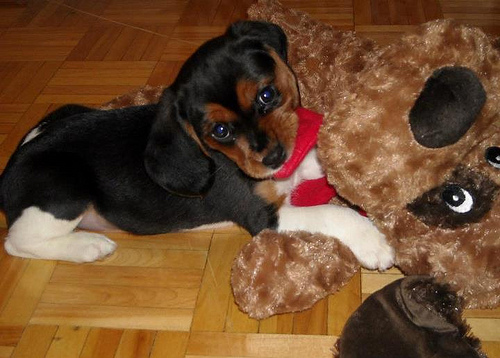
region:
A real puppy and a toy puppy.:
[31, 22, 488, 319]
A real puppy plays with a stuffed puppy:
[27, 11, 494, 255]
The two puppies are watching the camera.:
[23, 34, 488, 335]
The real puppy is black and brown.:
[6, 20, 346, 285]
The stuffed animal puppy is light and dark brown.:
[229, 8, 499, 339]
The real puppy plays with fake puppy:
[38, 14, 480, 339]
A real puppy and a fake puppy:
[29, 20, 499, 317]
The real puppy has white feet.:
[36, 26, 472, 336]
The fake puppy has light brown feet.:
[42, 25, 499, 323]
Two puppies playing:
[32, 22, 497, 338]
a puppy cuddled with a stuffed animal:
[4, 17, 318, 272]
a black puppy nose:
[260, 142, 294, 169]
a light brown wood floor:
[2, 1, 499, 352]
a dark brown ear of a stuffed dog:
[332, 271, 485, 355]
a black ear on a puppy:
[145, 96, 215, 193]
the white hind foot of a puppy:
[0, 225, 113, 262]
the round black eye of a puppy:
[261, 89, 277, 103]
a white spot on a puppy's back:
[18, 118, 50, 151]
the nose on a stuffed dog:
[409, 57, 488, 148]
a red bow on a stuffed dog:
[285, 105, 339, 211]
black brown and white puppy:
[5, 22, 397, 284]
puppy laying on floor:
[9, 21, 387, 278]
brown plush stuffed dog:
[249, 3, 498, 353]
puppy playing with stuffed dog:
[6, 20, 396, 276]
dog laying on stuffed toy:
[0, 20, 388, 268]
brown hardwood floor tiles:
[2, 5, 493, 354]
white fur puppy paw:
[273, 201, 404, 272]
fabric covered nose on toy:
[412, 63, 484, 148]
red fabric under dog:
[283, 111, 334, 212]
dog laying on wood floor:
[9, 21, 397, 273]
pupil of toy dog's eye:
[436, 184, 467, 209]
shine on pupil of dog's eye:
[261, 83, 271, 106]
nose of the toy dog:
[394, 64, 487, 178]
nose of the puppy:
[248, 132, 292, 174]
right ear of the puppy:
[123, 93, 211, 251]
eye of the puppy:
[206, 115, 228, 155]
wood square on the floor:
[4, 282, 207, 339]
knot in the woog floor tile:
[61, 317, 81, 341]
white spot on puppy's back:
[4, 110, 59, 152]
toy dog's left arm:
[241, 223, 360, 346]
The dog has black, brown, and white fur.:
[6, 30, 368, 280]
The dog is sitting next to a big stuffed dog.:
[131, 16, 496, 299]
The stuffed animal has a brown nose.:
[388, 65, 493, 156]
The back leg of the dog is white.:
[8, 220, 118, 268]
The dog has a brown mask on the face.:
[180, 70, 300, 180]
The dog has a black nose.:
[255, 141, 291, 174]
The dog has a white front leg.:
[275, 181, 401, 277]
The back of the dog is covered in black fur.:
[60, 120, 132, 172]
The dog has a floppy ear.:
[138, 80, 220, 208]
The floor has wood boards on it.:
[31, 281, 183, 347]